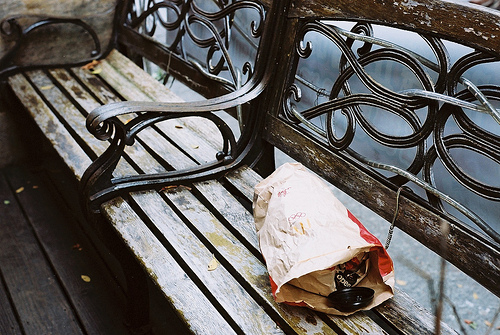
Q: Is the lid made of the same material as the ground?
A: No, the lid is made of plastic and the ground is made of wood.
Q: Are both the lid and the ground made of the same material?
A: No, the lid is made of plastic and the ground is made of wood.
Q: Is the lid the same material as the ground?
A: No, the lid is made of plastic and the ground is made of wood.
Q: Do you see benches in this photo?
A: Yes, there is a bench.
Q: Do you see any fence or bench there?
A: Yes, there is a bench.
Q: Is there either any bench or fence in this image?
A: Yes, there is a bench.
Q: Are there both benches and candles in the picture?
A: No, there is a bench but no candles.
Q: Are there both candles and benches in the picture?
A: No, there is a bench but no candles.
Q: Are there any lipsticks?
A: No, there are no lipsticks.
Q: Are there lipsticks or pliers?
A: No, there are no lipsticks or pliers.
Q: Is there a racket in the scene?
A: No, there are no rackets.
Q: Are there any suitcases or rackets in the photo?
A: No, there are no rackets or suitcases.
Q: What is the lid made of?
A: The lid is made of plastic.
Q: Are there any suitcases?
A: No, there are no suitcases.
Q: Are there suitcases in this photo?
A: No, there are no suitcases.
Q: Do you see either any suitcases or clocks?
A: No, there are no suitcases or clocks.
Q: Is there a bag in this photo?
A: Yes, there is a bag.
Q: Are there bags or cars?
A: Yes, there is a bag.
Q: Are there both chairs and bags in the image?
A: No, there is a bag but no chairs.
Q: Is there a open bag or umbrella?
A: Yes, there is an open bag.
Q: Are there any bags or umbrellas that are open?
A: Yes, the bag is open.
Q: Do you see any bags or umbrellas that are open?
A: Yes, the bag is open.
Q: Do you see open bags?
A: Yes, there is an open bag.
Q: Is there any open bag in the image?
A: Yes, there is an open bag.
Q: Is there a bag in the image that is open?
A: Yes, there is an open bag.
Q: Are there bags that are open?
A: Yes, there is a bag that is open.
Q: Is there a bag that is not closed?
A: Yes, there is a open bag.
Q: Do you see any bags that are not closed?
A: Yes, there is a open bag.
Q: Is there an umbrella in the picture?
A: No, there are no umbrellas.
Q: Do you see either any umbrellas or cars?
A: No, there are no umbrellas or cars.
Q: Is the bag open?
A: Yes, the bag is open.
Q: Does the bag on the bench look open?
A: Yes, the bag is open.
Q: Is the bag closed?
A: No, the bag is open.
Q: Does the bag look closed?
A: No, the bag is open.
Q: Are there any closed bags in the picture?
A: No, there is a bag but it is open.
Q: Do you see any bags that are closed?
A: No, there is a bag but it is open.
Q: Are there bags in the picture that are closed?
A: No, there is a bag but it is open.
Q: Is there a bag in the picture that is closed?
A: No, there is a bag but it is open.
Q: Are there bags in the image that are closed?
A: No, there is a bag but it is open.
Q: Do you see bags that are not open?
A: No, there is a bag but it is open.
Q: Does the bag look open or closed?
A: The bag is open.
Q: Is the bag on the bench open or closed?
A: The bag is open.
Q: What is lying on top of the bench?
A: The bag is lying on top of the bench.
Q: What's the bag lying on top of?
A: The bag is lying on top of the bench.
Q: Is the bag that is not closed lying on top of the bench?
A: Yes, the bag is lying on top of the bench.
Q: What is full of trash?
A: The bag is full of trash.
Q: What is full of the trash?
A: The bag is full of trash.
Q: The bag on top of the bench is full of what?
A: The bag is full of trash.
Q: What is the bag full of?
A: The bag is full of trash.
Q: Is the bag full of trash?
A: Yes, the bag is full of trash.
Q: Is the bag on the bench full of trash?
A: Yes, the bag is full of trash.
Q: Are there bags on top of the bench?
A: Yes, there is a bag on top of the bench.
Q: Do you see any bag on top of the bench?
A: Yes, there is a bag on top of the bench.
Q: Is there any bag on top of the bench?
A: Yes, there is a bag on top of the bench.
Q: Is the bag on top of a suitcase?
A: No, the bag is on top of a bench.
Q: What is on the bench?
A: The bag is on the bench.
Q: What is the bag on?
A: The bag is on the bench.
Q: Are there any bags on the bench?
A: Yes, there is a bag on the bench.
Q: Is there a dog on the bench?
A: No, there is a bag on the bench.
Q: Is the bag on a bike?
A: No, the bag is on a bench.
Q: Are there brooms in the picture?
A: No, there are no brooms.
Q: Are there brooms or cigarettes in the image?
A: No, there are no brooms or cigarettes.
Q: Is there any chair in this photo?
A: No, there are no chairs.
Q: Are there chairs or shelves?
A: No, there are no chairs or shelves.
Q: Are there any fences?
A: No, there are no fences.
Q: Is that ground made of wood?
A: Yes, the ground is made of wood.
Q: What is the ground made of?
A: The ground is made of wood.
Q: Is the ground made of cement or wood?
A: The ground is made of wood.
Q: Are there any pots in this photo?
A: No, there are no pots.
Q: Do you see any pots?
A: No, there are no pots.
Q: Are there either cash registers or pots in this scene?
A: No, there are no pots or cash registers.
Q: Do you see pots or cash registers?
A: No, there are no pots or cash registers.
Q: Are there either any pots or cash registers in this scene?
A: No, there are no pots or cash registers.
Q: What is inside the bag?
A: The trash is inside the bag.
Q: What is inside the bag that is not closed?
A: The trash is inside the bag.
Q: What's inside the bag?
A: The trash is inside the bag.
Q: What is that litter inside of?
A: The litter is inside the bag.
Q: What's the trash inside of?
A: The litter is inside the bag.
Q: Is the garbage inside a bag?
A: Yes, the garbage is inside a bag.